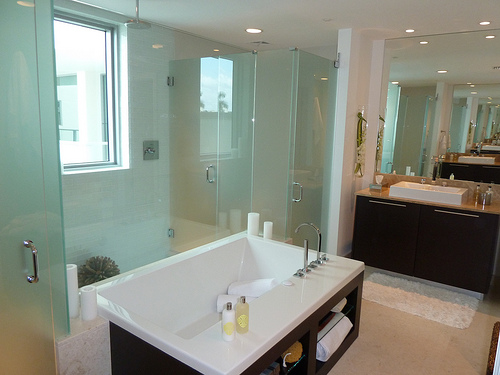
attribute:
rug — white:
[346, 246, 490, 323]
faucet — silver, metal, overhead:
[413, 142, 448, 190]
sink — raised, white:
[382, 169, 480, 211]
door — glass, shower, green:
[252, 28, 372, 295]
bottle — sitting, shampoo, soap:
[191, 287, 261, 359]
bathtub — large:
[73, 157, 380, 366]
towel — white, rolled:
[36, 246, 100, 328]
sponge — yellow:
[71, 242, 108, 286]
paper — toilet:
[314, 298, 367, 342]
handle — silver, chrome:
[9, 224, 50, 294]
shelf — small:
[264, 331, 313, 372]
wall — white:
[3, 21, 228, 221]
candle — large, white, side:
[373, 167, 388, 196]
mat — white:
[371, 260, 488, 337]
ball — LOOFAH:
[56, 227, 129, 285]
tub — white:
[115, 218, 302, 353]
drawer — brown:
[333, 191, 472, 256]